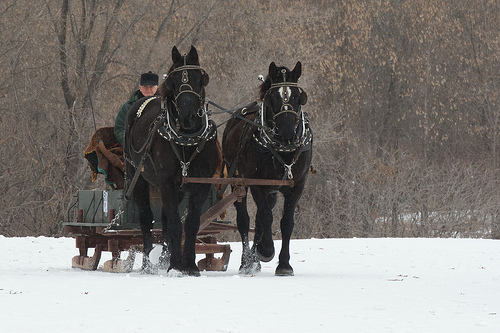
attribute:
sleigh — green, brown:
[43, 169, 303, 273]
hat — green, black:
[140, 60, 163, 92]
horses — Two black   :
[137, 32, 316, 281]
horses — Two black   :
[122, 42, 323, 293]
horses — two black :
[123, 38, 313, 270]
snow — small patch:
[324, 276, 437, 330]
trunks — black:
[60, 176, 76, 226]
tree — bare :
[53, 5, 169, 140]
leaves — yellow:
[350, 20, 370, 41]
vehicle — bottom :
[73, 246, 264, 279]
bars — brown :
[190, 166, 288, 233]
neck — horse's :
[172, 130, 286, 152]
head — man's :
[133, 63, 159, 104]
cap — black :
[136, 67, 158, 87]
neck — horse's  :
[165, 122, 215, 152]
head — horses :
[254, 62, 315, 172]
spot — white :
[276, 82, 291, 104]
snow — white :
[303, 246, 450, 306]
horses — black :
[144, 44, 326, 291]